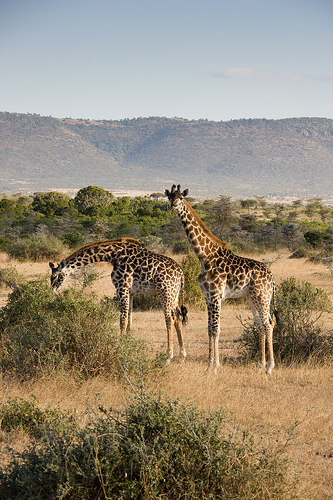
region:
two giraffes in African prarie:
[37, 182, 290, 403]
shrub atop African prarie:
[0, 342, 321, 494]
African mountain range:
[35, 80, 311, 224]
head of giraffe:
[158, 182, 190, 213]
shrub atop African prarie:
[237, 262, 331, 372]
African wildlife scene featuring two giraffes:
[38, 172, 296, 419]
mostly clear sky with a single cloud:
[4, 0, 326, 105]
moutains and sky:
[3, 42, 321, 213]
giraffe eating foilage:
[31, 227, 194, 368]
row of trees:
[3, 164, 161, 236]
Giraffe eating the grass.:
[37, 224, 190, 362]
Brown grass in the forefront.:
[198, 366, 328, 432]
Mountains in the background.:
[0, 106, 330, 195]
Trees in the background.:
[29, 185, 120, 218]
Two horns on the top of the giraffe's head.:
[162, 181, 185, 207]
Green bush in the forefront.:
[1, 278, 101, 364]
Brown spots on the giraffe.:
[166, 190, 280, 302]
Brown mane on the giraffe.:
[164, 184, 231, 254]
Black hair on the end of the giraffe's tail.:
[176, 266, 192, 326]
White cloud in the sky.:
[216, 62, 264, 82]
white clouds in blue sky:
[10, 12, 56, 42]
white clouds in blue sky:
[7, 55, 41, 88]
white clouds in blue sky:
[71, 40, 101, 67]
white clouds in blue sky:
[70, 65, 159, 119]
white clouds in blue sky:
[189, 36, 273, 95]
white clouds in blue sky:
[148, 62, 196, 93]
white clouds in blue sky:
[219, 30, 315, 73]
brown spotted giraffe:
[26, 202, 177, 380]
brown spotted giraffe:
[158, 175, 231, 243]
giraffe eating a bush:
[44, 229, 192, 369]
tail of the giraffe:
[270, 284, 283, 330]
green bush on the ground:
[53, 392, 288, 498]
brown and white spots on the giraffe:
[215, 256, 228, 266]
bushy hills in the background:
[66, 120, 156, 168]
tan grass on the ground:
[209, 375, 286, 409]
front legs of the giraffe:
[200, 298, 223, 380]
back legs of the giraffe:
[244, 297, 276, 375]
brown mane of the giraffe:
[88, 233, 138, 247]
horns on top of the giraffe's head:
[166, 184, 183, 193]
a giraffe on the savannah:
[165, 179, 288, 377]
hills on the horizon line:
[6, 99, 331, 195]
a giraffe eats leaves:
[47, 243, 190, 367]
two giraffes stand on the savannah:
[42, 181, 286, 375]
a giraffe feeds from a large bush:
[41, 236, 187, 369]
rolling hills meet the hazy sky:
[9, 104, 322, 180]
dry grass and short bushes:
[16, 341, 224, 459]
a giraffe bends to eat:
[40, 237, 186, 328]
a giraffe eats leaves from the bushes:
[48, 234, 130, 305]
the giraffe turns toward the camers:
[157, 179, 196, 226]